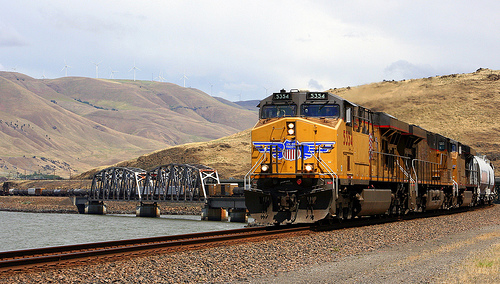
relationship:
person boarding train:
[384, 83, 482, 235] [253, 90, 484, 227]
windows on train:
[251, 96, 346, 129] [255, 94, 475, 215]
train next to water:
[242, 96, 475, 206] [0, 211, 236, 231]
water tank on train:
[470, 152, 496, 188] [252, 88, 497, 232]